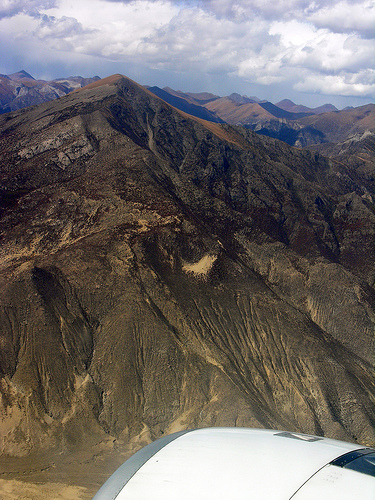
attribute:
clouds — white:
[147, 20, 284, 76]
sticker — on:
[280, 428, 318, 445]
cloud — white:
[0, 1, 68, 12]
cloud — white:
[248, 5, 374, 28]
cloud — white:
[26, 13, 226, 53]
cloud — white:
[237, 18, 369, 69]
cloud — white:
[241, 61, 371, 94]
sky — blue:
[7, 71, 371, 95]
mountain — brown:
[32, 154, 330, 402]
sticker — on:
[271, 427, 327, 446]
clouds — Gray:
[177, 19, 365, 89]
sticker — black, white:
[276, 431, 322, 440]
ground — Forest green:
[306, 97, 337, 128]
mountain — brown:
[37, 40, 373, 431]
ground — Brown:
[277, 97, 315, 146]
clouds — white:
[248, 12, 364, 87]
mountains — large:
[4, 68, 373, 426]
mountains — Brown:
[0, 83, 373, 499]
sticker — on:
[105, 9, 244, 78]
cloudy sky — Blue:
[268, 16, 352, 96]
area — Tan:
[178, 248, 219, 275]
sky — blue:
[21, 22, 105, 56]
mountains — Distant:
[10, 63, 304, 161]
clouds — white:
[0, 1, 373, 98]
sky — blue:
[139, 16, 306, 80]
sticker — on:
[273, 430, 324, 441]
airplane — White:
[88, 424, 374, 498]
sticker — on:
[199, 422, 324, 491]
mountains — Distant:
[0, 68, 371, 190]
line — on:
[219, 342, 269, 376]